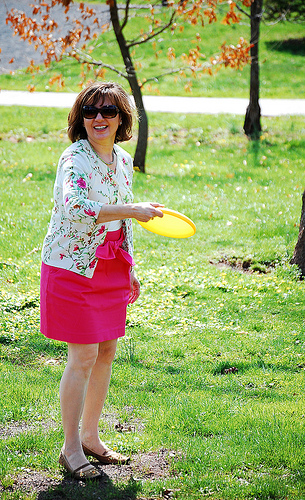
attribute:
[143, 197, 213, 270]
frisbee — yellow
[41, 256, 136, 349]
skirt — pink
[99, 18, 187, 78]
tree — bare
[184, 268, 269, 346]
grass — green, yellow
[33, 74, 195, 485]
lady — close, smiling, standing, playing, grinning, dressed, white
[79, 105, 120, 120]
sunglasses — black, dark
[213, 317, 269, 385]
grass — green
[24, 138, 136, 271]
jacket — printed